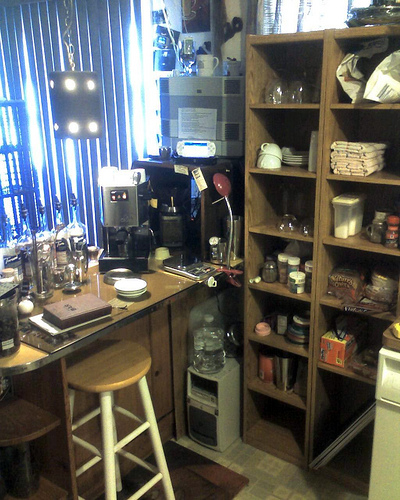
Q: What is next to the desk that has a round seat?
A: Stool.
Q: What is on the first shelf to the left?
A: Glasses.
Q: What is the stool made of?
A: Wood.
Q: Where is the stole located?
A: Under the desk.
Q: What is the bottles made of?
A: Glass.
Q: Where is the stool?
A: Under the desk.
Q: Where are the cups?
A: On the shelf.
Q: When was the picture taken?
A: Daytime.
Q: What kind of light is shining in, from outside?
A: Sunlight.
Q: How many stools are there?
A: One.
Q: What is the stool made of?
A: Wood.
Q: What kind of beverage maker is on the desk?
A: A coffee maker.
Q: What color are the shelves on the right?
A: Brown.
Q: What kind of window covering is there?
A: Blinds.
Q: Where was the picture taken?
A: In a small room of a house.